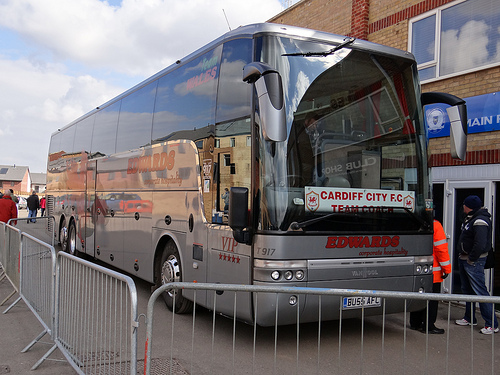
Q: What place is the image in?
A: It is at the street.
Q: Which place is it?
A: It is a street.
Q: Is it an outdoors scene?
A: Yes, it is outdoors.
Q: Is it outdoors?
A: Yes, it is outdoors.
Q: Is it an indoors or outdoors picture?
A: It is outdoors.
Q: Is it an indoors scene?
A: No, it is outdoors.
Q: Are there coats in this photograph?
A: Yes, there is a coat.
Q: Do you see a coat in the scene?
A: Yes, there is a coat.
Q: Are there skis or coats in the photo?
A: Yes, there is a coat.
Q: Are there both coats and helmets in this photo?
A: No, there is a coat but no helmets.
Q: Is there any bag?
A: No, there are no bags.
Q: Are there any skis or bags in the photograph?
A: No, there are no bags or skis.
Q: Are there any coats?
A: Yes, there is a coat.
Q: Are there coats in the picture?
A: Yes, there is a coat.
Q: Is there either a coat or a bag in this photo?
A: Yes, there is a coat.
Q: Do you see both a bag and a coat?
A: No, there is a coat but no bags.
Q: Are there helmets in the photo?
A: No, there are no helmets.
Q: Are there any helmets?
A: No, there are no helmets.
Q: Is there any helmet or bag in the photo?
A: No, there are no helmets or bags.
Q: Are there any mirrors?
A: Yes, there is a mirror.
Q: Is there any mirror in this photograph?
A: Yes, there is a mirror.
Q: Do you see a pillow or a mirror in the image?
A: Yes, there is a mirror.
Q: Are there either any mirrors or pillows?
A: Yes, there is a mirror.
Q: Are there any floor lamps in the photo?
A: No, there are no floor lamps.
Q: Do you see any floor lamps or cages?
A: No, there are no floor lamps or cages.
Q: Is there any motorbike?
A: No, there are no motorcycles.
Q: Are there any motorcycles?
A: No, there are no motorcycles.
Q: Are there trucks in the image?
A: No, there are no trucks.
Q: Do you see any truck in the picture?
A: No, there are no trucks.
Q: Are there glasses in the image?
A: No, there are no glasses.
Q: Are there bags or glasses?
A: No, there are no glasses or bags.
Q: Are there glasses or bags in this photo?
A: No, there are no glasses or bags.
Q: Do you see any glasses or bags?
A: No, there are no glasses or bags.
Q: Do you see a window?
A: Yes, there are windows.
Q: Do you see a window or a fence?
A: Yes, there are windows.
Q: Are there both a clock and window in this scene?
A: No, there are windows but no clocks.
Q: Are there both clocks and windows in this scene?
A: No, there are windows but no clocks.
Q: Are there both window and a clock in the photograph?
A: No, there are windows but no clocks.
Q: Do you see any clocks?
A: No, there are no clocks.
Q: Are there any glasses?
A: No, there are no glasses.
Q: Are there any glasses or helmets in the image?
A: No, there are no glasses or helmets.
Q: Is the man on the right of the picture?
A: Yes, the man is on the right of the image.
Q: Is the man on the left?
A: No, the man is on the right of the image.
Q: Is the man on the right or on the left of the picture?
A: The man is on the right of the image.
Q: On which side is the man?
A: The man is on the right of the image.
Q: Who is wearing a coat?
A: The man is wearing a coat.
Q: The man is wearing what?
A: The man is wearing a coat.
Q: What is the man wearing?
A: The man is wearing a coat.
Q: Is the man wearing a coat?
A: Yes, the man is wearing a coat.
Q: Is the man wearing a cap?
A: No, the man is wearing a coat.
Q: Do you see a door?
A: Yes, there is a door.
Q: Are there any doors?
A: Yes, there is a door.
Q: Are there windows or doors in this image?
A: Yes, there is a door.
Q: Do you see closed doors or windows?
A: Yes, there is a closed door.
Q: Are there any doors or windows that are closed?
A: Yes, the door is closed.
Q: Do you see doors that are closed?
A: Yes, there is a closed door.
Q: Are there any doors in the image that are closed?
A: Yes, there is a door that is closed.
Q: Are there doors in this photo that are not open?
A: Yes, there is an closed door.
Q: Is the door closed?
A: Yes, the door is closed.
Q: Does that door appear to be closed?
A: Yes, the door is closed.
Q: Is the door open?
A: No, the door is closed.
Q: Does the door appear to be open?
A: No, the door is closed.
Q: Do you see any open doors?
A: No, there is a door but it is closed.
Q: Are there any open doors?
A: No, there is a door but it is closed.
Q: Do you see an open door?
A: No, there is a door but it is closed.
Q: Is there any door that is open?
A: No, there is a door but it is closed.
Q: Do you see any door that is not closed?
A: No, there is a door but it is closed.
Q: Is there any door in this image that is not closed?
A: No, there is a door but it is closed.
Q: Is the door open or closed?
A: The door is closed.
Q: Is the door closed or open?
A: The door is closed.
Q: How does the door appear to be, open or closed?
A: The door is closed.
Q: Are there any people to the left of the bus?
A: Yes, there are people to the left of the bus.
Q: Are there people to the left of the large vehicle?
A: Yes, there are people to the left of the bus.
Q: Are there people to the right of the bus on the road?
A: No, the people are to the left of the bus.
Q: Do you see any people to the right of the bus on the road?
A: No, the people are to the left of the bus.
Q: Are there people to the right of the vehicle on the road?
A: No, the people are to the left of the bus.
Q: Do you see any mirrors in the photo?
A: Yes, there is a mirror.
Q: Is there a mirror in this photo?
A: Yes, there is a mirror.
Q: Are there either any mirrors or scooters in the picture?
A: Yes, there is a mirror.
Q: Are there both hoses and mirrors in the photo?
A: No, there is a mirror but no hoses.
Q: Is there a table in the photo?
A: No, there are no tables.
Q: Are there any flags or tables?
A: No, there are no tables or flags.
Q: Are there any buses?
A: Yes, there is a bus.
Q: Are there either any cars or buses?
A: Yes, there is a bus.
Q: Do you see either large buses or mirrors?
A: Yes, there is a large bus.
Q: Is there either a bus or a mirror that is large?
A: Yes, the bus is large.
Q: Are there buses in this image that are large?
A: Yes, there is a large bus.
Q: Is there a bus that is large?
A: Yes, there is a bus that is large.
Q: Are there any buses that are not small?
A: Yes, there is a large bus.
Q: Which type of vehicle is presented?
A: The vehicle is a bus.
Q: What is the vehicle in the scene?
A: The vehicle is a bus.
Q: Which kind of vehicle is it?
A: The vehicle is a bus.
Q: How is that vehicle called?
A: This is a bus.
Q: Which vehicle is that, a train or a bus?
A: This is a bus.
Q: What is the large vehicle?
A: The vehicle is a bus.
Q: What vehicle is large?
A: The vehicle is a bus.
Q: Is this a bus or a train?
A: This is a bus.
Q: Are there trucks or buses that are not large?
A: No, there is a bus but it is large.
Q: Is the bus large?
A: Yes, the bus is large.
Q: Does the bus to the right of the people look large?
A: Yes, the bus is large.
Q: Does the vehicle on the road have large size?
A: Yes, the bus is large.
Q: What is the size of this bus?
A: The bus is large.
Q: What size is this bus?
A: The bus is large.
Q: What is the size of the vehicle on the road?
A: The bus is large.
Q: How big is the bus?
A: The bus is large.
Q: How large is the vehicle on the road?
A: The bus is large.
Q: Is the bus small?
A: No, the bus is large.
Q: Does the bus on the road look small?
A: No, the bus is large.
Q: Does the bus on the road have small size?
A: No, the bus is large.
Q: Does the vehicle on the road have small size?
A: No, the bus is large.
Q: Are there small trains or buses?
A: No, there is a bus but it is large.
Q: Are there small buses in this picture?
A: No, there is a bus but it is large.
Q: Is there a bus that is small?
A: No, there is a bus but it is large.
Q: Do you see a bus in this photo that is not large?
A: No, there is a bus but it is large.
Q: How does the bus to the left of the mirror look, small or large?
A: The bus is large.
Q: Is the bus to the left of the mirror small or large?
A: The bus is large.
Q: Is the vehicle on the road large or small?
A: The bus is large.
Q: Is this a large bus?
A: Yes, this is a large bus.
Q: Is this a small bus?
A: No, this is a large bus.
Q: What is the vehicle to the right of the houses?
A: The vehicle is a bus.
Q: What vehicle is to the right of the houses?
A: The vehicle is a bus.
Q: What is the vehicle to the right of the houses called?
A: The vehicle is a bus.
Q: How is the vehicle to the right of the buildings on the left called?
A: The vehicle is a bus.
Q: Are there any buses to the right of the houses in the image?
A: Yes, there is a bus to the right of the houses.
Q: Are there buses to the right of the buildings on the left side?
A: Yes, there is a bus to the right of the houses.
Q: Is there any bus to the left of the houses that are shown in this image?
A: No, the bus is to the right of the houses.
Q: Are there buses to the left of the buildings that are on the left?
A: No, the bus is to the right of the houses.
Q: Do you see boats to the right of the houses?
A: No, there is a bus to the right of the houses.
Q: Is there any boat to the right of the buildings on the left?
A: No, there is a bus to the right of the houses.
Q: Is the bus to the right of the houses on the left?
A: Yes, the bus is to the right of the houses.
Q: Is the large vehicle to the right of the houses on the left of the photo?
A: Yes, the bus is to the right of the houses.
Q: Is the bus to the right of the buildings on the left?
A: Yes, the bus is to the right of the houses.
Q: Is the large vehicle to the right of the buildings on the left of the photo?
A: Yes, the bus is to the right of the houses.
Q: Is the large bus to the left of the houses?
A: No, the bus is to the right of the houses.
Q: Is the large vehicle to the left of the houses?
A: No, the bus is to the right of the houses.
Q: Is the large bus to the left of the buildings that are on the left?
A: No, the bus is to the right of the houses.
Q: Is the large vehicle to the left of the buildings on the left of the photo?
A: No, the bus is to the right of the houses.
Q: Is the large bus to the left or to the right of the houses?
A: The bus is to the right of the houses.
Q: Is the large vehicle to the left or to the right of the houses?
A: The bus is to the right of the houses.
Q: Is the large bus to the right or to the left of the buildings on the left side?
A: The bus is to the right of the houses.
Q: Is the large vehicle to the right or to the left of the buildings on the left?
A: The bus is to the right of the houses.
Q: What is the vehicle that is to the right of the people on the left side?
A: The vehicle is a bus.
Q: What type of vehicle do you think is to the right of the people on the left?
A: The vehicle is a bus.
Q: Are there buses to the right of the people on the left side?
A: Yes, there is a bus to the right of the people.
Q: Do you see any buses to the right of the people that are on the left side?
A: Yes, there is a bus to the right of the people.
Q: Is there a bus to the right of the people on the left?
A: Yes, there is a bus to the right of the people.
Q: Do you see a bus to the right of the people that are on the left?
A: Yes, there is a bus to the right of the people.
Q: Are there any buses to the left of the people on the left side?
A: No, the bus is to the right of the people.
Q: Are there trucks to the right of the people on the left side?
A: No, there is a bus to the right of the people.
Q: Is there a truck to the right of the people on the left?
A: No, there is a bus to the right of the people.